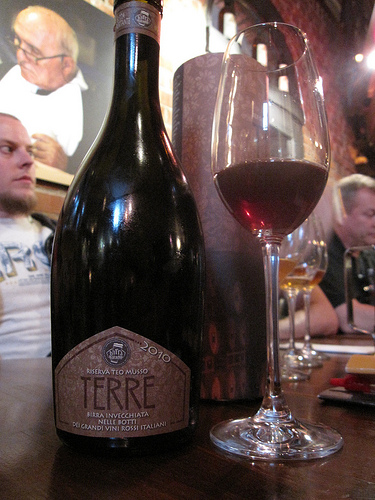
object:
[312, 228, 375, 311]
shirt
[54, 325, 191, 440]
label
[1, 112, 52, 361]
man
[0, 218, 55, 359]
shirt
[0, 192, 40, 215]
beard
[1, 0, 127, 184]
painting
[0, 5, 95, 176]
man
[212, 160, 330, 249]
wine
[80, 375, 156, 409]
terre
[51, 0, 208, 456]
black bottle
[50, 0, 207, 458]
wine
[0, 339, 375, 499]
table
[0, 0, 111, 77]
screen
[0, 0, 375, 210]
wall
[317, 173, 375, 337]
man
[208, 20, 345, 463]
glass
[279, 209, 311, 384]
glass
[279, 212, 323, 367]
glass